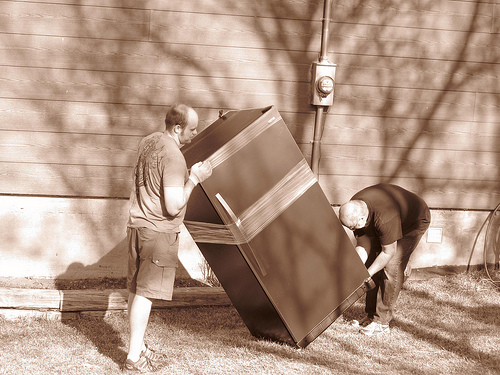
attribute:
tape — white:
[182, 159, 319, 248]